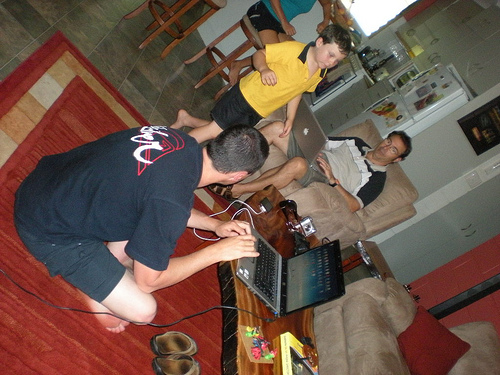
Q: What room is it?
A: It is a kitchen.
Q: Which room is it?
A: It is a kitchen.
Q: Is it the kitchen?
A: Yes, it is the kitchen.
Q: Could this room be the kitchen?
A: Yes, it is the kitchen.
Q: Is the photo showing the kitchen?
A: Yes, it is showing the kitchen.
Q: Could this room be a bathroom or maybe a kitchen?
A: It is a kitchen.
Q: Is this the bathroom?
A: No, it is the kitchen.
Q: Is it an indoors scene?
A: Yes, it is indoors.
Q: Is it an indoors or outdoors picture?
A: It is indoors.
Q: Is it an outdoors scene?
A: No, it is indoors.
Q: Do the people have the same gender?
A: No, they are both male and female.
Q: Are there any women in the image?
A: No, there are no women.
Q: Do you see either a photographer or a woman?
A: No, there are no women or photographers.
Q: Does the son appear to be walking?
A: Yes, the son is walking.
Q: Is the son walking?
A: Yes, the son is walking.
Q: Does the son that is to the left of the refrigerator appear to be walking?
A: Yes, the son is walking.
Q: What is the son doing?
A: The son is walking.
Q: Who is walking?
A: The son is walking.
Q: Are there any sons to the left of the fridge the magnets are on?
A: Yes, there is a son to the left of the fridge.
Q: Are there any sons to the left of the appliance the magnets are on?
A: Yes, there is a son to the left of the fridge.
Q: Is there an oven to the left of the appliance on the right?
A: No, there is a son to the left of the fridge.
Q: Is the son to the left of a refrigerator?
A: Yes, the son is to the left of a refrigerator.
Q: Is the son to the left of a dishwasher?
A: No, the son is to the left of a refrigerator.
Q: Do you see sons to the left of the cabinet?
A: Yes, there is a son to the left of the cabinet.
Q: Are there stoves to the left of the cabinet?
A: No, there is a son to the left of the cabinet.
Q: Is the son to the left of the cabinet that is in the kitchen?
A: Yes, the son is to the left of the cabinet.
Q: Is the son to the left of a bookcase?
A: No, the son is to the left of the cabinet.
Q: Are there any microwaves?
A: No, there are no microwaves.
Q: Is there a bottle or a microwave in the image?
A: No, there are no microwaves or bottles.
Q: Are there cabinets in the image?
A: Yes, there is a cabinet.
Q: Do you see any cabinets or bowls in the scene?
A: Yes, there is a cabinet.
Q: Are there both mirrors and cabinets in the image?
A: No, there is a cabinet but no mirrors.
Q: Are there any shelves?
A: No, there are no shelves.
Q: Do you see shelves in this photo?
A: No, there are no shelves.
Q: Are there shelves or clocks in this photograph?
A: No, there are no shelves or clocks.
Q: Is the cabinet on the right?
A: Yes, the cabinet is on the right of the image.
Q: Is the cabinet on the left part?
A: No, the cabinet is on the right of the image.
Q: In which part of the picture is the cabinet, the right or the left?
A: The cabinet is on the right of the image.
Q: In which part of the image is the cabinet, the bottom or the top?
A: The cabinet is in the top of the image.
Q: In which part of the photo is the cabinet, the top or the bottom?
A: The cabinet is in the top of the image.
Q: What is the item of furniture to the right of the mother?
A: The piece of furniture is a cabinet.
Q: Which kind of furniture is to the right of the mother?
A: The piece of furniture is a cabinet.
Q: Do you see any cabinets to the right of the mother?
A: Yes, there is a cabinet to the right of the mother.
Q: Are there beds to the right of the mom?
A: No, there is a cabinet to the right of the mom.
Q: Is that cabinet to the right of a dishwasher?
A: No, the cabinet is to the right of a mother.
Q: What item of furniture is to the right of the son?
A: The piece of furniture is a cabinet.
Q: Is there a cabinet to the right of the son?
A: Yes, there is a cabinet to the right of the son.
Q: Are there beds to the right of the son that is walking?
A: No, there is a cabinet to the right of the son.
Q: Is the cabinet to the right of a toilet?
A: No, the cabinet is to the right of the son.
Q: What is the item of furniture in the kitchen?
A: The piece of furniture is a cabinet.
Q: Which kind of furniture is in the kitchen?
A: The piece of furniture is a cabinet.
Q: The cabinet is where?
A: The cabinet is in the kitchen.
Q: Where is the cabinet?
A: The cabinet is in the kitchen.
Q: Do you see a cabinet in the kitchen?
A: Yes, there is a cabinet in the kitchen.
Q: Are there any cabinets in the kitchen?
A: Yes, there is a cabinet in the kitchen.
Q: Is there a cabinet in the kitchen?
A: Yes, there is a cabinet in the kitchen.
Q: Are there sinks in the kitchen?
A: No, there is a cabinet in the kitchen.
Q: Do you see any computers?
A: Yes, there is a computer.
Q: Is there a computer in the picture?
A: Yes, there is a computer.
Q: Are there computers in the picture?
A: Yes, there is a computer.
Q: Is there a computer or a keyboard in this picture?
A: Yes, there is a computer.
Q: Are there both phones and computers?
A: No, there is a computer but no phones.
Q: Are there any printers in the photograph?
A: No, there are no printers.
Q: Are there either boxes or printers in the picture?
A: No, there are no printers or boxes.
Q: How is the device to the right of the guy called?
A: The device is a computer.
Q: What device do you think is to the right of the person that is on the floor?
A: The device is a computer.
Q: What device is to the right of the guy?
A: The device is a computer.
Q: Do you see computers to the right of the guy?
A: Yes, there is a computer to the right of the guy.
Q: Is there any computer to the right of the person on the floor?
A: Yes, there is a computer to the right of the guy.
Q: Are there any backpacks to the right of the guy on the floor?
A: No, there is a computer to the right of the guy.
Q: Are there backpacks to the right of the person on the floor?
A: No, there is a computer to the right of the guy.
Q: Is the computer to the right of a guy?
A: Yes, the computer is to the right of a guy.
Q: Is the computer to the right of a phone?
A: No, the computer is to the right of a guy.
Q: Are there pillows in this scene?
A: Yes, there is a pillow.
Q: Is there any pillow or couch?
A: Yes, there is a pillow.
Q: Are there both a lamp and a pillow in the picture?
A: No, there is a pillow but no lamps.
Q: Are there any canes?
A: No, there are no canes.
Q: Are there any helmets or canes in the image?
A: No, there are no canes or helmets.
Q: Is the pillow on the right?
A: Yes, the pillow is on the right of the image.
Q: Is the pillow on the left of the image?
A: No, the pillow is on the right of the image.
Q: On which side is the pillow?
A: The pillow is on the right of the image.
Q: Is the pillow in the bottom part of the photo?
A: Yes, the pillow is in the bottom of the image.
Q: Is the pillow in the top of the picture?
A: No, the pillow is in the bottom of the image.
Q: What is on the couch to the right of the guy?
A: The pillow is on the couch.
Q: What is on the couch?
A: The pillow is on the couch.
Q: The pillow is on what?
A: The pillow is on the couch.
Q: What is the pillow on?
A: The pillow is on the couch.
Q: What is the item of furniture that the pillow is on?
A: The piece of furniture is a couch.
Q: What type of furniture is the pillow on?
A: The pillow is on the couch.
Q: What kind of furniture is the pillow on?
A: The pillow is on the couch.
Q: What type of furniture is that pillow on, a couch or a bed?
A: The pillow is on a couch.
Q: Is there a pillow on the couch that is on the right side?
A: Yes, there is a pillow on the couch.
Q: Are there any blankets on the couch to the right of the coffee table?
A: No, there is a pillow on the couch.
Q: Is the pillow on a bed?
A: No, the pillow is on the couch.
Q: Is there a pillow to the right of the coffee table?
A: Yes, there is a pillow to the right of the coffee table.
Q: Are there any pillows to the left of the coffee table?
A: No, the pillow is to the right of the coffee table.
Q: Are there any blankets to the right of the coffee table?
A: No, there is a pillow to the right of the coffee table.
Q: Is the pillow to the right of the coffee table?
A: Yes, the pillow is to the right of the coffee table.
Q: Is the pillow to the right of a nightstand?
A: No, the pillow is to the right of the coffee table.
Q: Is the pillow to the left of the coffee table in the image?
A: No, the pillow is to the right of the coffee table.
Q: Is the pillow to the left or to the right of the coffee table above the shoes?
A: The pillow is to the right of the coffee table.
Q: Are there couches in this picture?
A: Yes, there is a couch.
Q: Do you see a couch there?
A: Yes, there is a couch.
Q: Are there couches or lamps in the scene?
A: Yes, there is a couch.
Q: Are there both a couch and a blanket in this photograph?
A: No, there is a couch but no blankets.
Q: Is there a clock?
A: No, there are no clocks.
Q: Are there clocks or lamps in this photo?
A: No, there are no clocks or lamps.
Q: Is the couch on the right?
A: Yes, the couch is on the right of the image.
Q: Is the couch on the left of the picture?
A: No, the couch is on the right of the image.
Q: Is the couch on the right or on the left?
A: The couch is on the right of the image.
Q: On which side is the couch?
A: The couch is on the right of the image.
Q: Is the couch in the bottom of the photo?
A: Yes, the couch is in the bottom of the image.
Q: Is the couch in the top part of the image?
A: No, the couch is in the bottom of the image.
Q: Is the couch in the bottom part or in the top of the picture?
A: The couch is in the bottom of the image.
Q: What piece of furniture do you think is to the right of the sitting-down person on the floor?
A: The piece of furniture is a couch.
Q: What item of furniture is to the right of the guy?
A: The piece of furniture is a couch.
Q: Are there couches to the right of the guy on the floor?
A: Yes, there is a couch to the right of the guy.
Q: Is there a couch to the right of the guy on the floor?
A: Yes, there is a couch to the right of the guy.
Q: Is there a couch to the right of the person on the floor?
A: Yes, there is a couch to the right of the guy.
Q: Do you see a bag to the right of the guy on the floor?
A: No, there is a couch to the right of the guy.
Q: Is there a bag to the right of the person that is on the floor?
A: No, there is a couch to the right of the guy.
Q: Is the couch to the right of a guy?
A: Yes, the couch is to the right of a guy.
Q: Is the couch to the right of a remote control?
A: No, the couch is to the right of a guy.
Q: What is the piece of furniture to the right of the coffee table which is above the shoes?
A: The piece of furniture is a couch.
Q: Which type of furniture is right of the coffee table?
A: The piece of furniture is a couch.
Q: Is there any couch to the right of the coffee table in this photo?
A: Yes, there is a couch to the right of the coffee table.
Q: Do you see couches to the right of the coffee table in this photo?
A: Yes, there is a couch to the right of the coffee table.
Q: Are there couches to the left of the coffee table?
A: No, the couch is to the right of the coffee table.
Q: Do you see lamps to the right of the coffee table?
A: No, there is a couch to the right of the coffee table.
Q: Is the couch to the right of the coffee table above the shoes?
A: Yes, the couch is to the right of the coffee table.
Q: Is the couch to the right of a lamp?
A: No, the couch is to the right of the coffee table.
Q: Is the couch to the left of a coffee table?
A: No, the couch is to the right of a coffee table.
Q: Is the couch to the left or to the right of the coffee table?
A: The couch is to the right of the coffee table.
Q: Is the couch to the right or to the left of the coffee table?
A: The couch is to the right of the coffee table.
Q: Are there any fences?
A: No, there are no fences.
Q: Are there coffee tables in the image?
A: Yes, there is a coffee table.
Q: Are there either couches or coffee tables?
A: Yes, there is a coffee table.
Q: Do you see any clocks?
A: No, there are no clocks.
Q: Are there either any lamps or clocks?
A: No, there are no clocks or lamps.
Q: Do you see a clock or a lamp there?
A: No, there are no clocks or lamps.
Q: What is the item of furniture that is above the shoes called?
A: The piece of furniture is a coffee table.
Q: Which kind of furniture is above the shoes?
A: The piece of furniture is a coffee table.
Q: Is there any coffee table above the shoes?
A: Yes, there is a coffee table above the shoes.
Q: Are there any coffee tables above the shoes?
A: Yes, there is a coffee table above the shoes.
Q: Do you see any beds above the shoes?
A: No, there is a coffee table above the shoes.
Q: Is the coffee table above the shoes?
A: Yes, the coffee table is above the shoes.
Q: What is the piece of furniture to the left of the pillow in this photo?
A: The piece of furniture is a coffee table.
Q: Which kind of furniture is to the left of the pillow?
A: The piece of furniture is a coffee table.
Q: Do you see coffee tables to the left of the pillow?
A: Yes, there is a coffee table to the left of the pillow.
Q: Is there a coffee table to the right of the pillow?
A: No, the coffee table is to the left of the pillow.